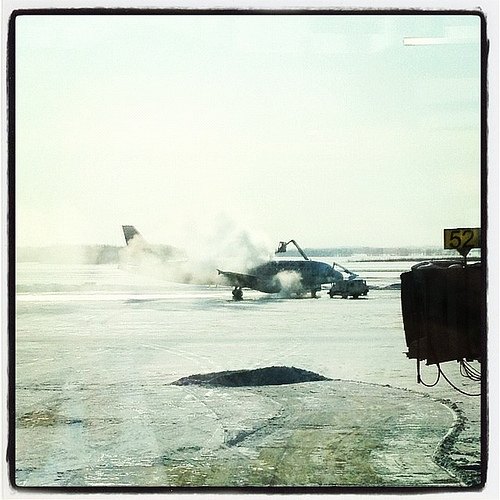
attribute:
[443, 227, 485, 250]
number sign — yellow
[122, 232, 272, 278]
smoke — white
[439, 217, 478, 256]
number 52 — black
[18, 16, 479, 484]
day — misty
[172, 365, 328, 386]
dirt — gray